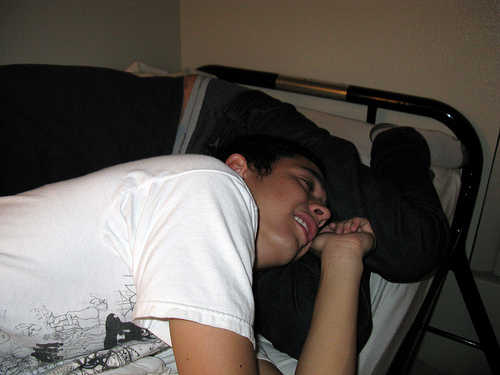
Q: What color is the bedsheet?
A: White.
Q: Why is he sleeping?
A: He is tired.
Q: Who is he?
A: A boy.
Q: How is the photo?
A: Clear.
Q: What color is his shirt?
A: White.